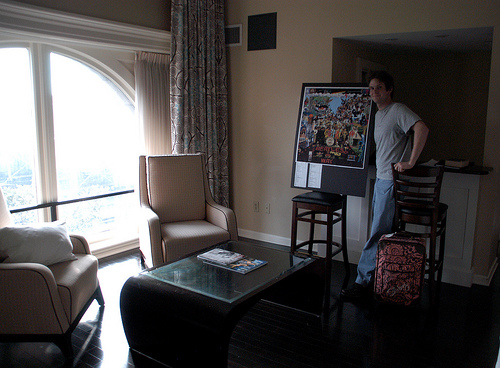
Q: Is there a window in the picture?
A: Yes, there is a window.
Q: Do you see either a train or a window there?
A: Yes, there is a window.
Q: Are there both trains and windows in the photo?
A: No, there is a window but no trains.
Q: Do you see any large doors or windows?
A: Yes, there is a large window.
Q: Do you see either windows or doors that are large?
A: Yes, the window is large.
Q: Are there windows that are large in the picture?
A: Yes, there is a large window.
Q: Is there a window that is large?
A: Yes, there is a window that is large.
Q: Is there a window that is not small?
A: Yes, there is a large window.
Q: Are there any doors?
A: No, there are no doors.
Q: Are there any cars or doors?
A: No, there are no doors or cars.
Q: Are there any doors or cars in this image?
A: No, there are no doors or cars.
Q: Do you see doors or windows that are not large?
A: No, there is a window but it is large.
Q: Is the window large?
A: Yes, the window is large.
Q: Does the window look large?
A: Yes, the window is large.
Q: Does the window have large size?
A: Yes, the window is large.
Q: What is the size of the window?
A: The window is large.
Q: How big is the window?
A: The window is large.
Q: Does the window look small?
A: No, the window is large.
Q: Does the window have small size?
A: No, the window is large.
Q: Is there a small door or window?
A: No, there is a window but it is large.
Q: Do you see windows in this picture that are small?
A: No, there is a window but it is large.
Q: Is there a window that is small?
A: No, there is a window but it is large.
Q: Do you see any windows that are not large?
A: No, there is a window but it is large.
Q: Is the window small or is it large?
A: The window is large.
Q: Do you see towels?
A: No, there are no towels.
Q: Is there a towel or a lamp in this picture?
A: No, there are no towels or lamps.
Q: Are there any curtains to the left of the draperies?
A: Yes, there is a curtain to the left of the draperies.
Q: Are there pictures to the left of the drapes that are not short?
A: No, there is a curtain to the left of the draperies.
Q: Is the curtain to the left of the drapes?
A: Yes, the curtain is to the left of the drapes.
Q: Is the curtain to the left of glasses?
A: No, the curtain is to the left of the drapes.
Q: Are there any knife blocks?
A: No, there are no knife blocks.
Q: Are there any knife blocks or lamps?
A: No, there are no knife blocks or lamps.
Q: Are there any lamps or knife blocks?
A: No, there are no knife blocks or lamps.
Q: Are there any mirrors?
A: No, there are no mirrors.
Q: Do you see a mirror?
A: No, there are no mirrors.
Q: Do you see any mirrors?
A: No, there are no mirrors.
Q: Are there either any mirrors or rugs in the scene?
A: No, there are no mirrors or rugs.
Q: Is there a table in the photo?
A: Yes, there is a table.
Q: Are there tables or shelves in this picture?
A: Yes, there is a table.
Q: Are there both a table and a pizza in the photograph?
A: No, there is a table but no pizzas.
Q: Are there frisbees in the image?
A: No, there are no frisbees.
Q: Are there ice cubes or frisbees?
A: No, there are no frisbees or ice cubes.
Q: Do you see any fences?
A: No, there are no fences.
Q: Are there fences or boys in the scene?
A: No, there are no fences or boys.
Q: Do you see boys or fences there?
A: No, there are no fences or boys.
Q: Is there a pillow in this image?
A: Yes, there is a pillow.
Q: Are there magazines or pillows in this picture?
A: Yes, there is a pillow.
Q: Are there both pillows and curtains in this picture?
A: Yes, there are both a pillow and a curtain.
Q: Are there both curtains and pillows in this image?
A: Yes, there are both a pillow and a curtain.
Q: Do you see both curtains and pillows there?
A: Yes, there are both a pillow and a curtain.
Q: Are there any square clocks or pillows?
A: Yes, there is a square pillow.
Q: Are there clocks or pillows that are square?
A: Yes, the pillow is square.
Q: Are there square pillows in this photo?
A: Yes, there is a square pillow.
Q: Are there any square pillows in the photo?
A: Yes, there is a square pillow.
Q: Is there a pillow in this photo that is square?
A: Yes, there is a pillow that is square.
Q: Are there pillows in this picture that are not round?
A: Yes, there is a square pillow.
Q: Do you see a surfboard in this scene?
A: No, there are no surfboards.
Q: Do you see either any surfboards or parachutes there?
A: No, there are no surfboards or parachutes.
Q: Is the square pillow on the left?
A: Yes, the pillow is on the left of the image.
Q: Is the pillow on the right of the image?
A: No, the pillow is on the left of the image.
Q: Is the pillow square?
A: Yes, the pillow is square.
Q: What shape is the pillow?
A: The pillow is square.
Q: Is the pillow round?
A: No, the pillow is square.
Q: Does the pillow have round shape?
A: No, the pillow is square.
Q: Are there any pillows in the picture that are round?
A: No, there is a pillow but it is square.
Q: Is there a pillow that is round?
A: No, there is a pillow but it is square.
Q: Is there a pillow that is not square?
A: No, there is a pillow but it is square.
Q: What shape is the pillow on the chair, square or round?
A: The pillow is square.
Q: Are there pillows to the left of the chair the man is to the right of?
A: Yes, there is a pillow to the left of the chair.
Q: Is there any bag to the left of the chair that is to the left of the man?
A: No, there is a pillow to the left of the chair.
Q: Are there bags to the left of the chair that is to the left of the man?
A: No, there is a pillow to the left of the chair.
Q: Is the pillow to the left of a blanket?
A: No, the pillow is to the left of a chair.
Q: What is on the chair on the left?
A: The pillow is on the chair.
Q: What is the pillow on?
A: The pillow is on the chair.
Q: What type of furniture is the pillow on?
A: The pillow is on the chair.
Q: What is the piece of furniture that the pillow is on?
A: The piece of furniture is a chair.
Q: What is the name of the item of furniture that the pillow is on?
A: The piece of furniture is a chair.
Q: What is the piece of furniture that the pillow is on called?
A: The piece of furniture is a chair.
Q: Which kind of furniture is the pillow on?
A: The pillow is on the chair.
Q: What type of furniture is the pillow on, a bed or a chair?
A: The pillow is on a chair.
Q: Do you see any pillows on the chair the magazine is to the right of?
A: Yes, there is a pillow on the chair.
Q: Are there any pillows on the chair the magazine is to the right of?
A: Yes, there is a pillow on the chair.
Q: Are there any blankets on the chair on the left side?
A: No, there is a pillow on the chair.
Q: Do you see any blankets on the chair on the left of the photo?
A: No, there is a pillow on the chair.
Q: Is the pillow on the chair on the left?
A: Yes, the pillow is on the chair.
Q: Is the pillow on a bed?
A: No, the pillow is on the chair.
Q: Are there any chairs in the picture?
A: Yes, there is a chair.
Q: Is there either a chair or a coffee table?
A: Yes, there is a chair.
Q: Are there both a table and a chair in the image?
A: Yes, there are both a chair and a table.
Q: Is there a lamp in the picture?
A: No, there are no lamps.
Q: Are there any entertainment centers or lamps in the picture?
A: No, there are no lamps or entertainment centers.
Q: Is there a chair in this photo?
A: Yes, there is a chair.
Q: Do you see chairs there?
A: Yes, there is a chair.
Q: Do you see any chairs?
A: Yes, there is a chair.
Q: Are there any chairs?
A: Yes, there is a chair.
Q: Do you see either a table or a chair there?
A: Yes, there is a chair.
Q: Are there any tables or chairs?
A: Yes, there is a chair.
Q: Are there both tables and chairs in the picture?
A: Yes, there are both a chair and a table.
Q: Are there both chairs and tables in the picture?
A: Yes, there are both a chair and a table.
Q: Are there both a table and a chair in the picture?
A: Yes, there are both a chair and a table.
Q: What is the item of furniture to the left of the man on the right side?
A: The piece of furniture is a chair.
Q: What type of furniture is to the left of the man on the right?
A: The piece of furniture is a chair.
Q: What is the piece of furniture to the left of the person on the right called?
A: The piece of furniture is a chair.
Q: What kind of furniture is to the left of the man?
A: The piece of furniture is a chair.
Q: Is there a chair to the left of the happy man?
A: Yes, there is a chair to the left of the man.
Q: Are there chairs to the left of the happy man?
A: Yes, there is a chair to the left of the man.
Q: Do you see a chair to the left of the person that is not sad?
A: Yes, there is a chair to the left of the man.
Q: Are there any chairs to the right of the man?
A: No, the chair is to the left of the man.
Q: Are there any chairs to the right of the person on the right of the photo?
A: No, the chair is to the left of the man.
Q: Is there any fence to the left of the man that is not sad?
A: No, there is a chair to the left of the man.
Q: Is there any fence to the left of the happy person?
A: No, there is a chair to the left of the man.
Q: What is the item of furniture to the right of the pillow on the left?
A: The piece of furniture is a chair.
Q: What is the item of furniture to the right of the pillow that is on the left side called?
A: The piece of furniture is a chair.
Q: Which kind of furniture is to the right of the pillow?
A: The piece of furniture is a chair.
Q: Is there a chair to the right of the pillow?
A: Yes, there is a chair to the right of the pillow.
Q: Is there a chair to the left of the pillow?
A: No, the chair is to the right of the pillow.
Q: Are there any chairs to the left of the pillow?
A: No, the chair is to the right of the pillow.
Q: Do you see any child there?
A: No, there are no children.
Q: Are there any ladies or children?
A: No, there are no children or ladies.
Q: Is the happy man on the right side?
A: Yes, the man is on the right of the image.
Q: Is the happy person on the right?
A: Yes, the man is on the right of the image.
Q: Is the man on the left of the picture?
A: No, the man is on the right of the image.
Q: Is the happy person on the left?
A: No, the man is on the right of the image.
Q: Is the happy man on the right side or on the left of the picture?
A: The man is on the right of the image.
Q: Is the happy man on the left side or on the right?
A: The man is on the right of the image.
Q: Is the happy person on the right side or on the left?
A: The man is on the right of the image.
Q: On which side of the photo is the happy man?
A: The man is on the right of the image.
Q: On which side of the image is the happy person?
A: The man is on the right of the image.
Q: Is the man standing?
A: Yes, the man is standing.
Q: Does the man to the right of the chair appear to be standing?
A: Yes, the man is standing.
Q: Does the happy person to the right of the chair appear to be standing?
A: Yes, the man is standing.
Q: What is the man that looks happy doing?
A: The man is standing.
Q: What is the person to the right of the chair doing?
A: The man is standing.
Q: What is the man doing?
A: The man is standing.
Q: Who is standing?
A: The man is standing.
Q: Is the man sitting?
A: No, the man is standing.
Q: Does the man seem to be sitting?
A: No, the man is standing.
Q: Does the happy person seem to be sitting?
A: No, the man is standing.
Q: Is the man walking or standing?
A: The man is standing.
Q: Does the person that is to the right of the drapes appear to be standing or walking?
A: The man is standing.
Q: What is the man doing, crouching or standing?
A: The man is standing.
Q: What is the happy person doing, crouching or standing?
A: The man is standing.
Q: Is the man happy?
A: Yes, the man is happy.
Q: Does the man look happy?
A: Yes, the man is happy.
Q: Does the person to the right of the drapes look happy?
A: Yes, the man is happy.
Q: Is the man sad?
A: No, the man is happy.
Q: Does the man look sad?
A: No, the man is happy.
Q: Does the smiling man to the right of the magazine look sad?
A: No, the man is happy.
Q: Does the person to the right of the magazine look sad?
A: No, the man is happy.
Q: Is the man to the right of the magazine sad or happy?
A: The man is happy.